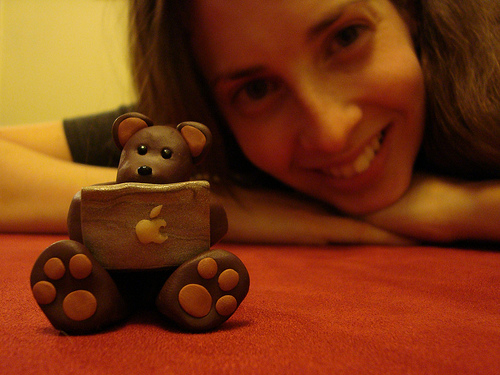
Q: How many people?
A: 1.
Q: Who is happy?
A: Girl.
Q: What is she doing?
A: Laying her head down.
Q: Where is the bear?
A: On table.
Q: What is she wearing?
A: Tee shirt.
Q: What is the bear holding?
A: Apple logo.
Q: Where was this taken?
A: A bedroom.